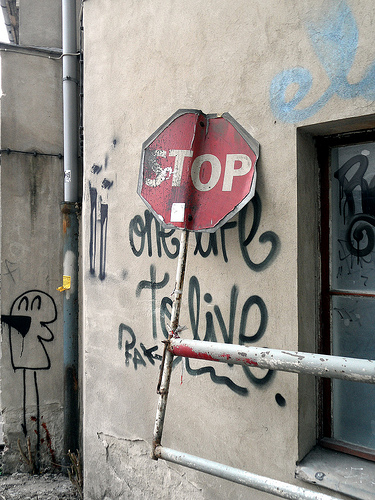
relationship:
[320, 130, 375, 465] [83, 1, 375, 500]
gate on building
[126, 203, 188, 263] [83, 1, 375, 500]
word on building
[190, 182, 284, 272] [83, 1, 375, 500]
word on building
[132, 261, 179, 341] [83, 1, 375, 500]
word on building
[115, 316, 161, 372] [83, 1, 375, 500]
word on building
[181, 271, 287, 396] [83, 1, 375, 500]
word on building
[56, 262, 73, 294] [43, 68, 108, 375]
tag on pipe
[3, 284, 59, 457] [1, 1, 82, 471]
graffiti on a wall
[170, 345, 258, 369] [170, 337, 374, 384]
paint on side of pole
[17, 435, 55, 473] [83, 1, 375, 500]
weed by building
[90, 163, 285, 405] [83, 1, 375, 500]
graffiti on building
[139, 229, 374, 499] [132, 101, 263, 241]
poles attached to sign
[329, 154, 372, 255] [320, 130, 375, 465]
graffiti on gate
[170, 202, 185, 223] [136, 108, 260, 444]
sticker on stop sign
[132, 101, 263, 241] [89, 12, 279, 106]
sign leans on a wall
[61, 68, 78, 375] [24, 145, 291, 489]
pipe next to building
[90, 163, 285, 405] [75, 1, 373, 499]
graffiti on building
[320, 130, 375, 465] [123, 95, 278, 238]
gate near sign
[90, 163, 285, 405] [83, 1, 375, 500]
graffiti painted on building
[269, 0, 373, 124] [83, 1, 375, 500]
letters painted on building